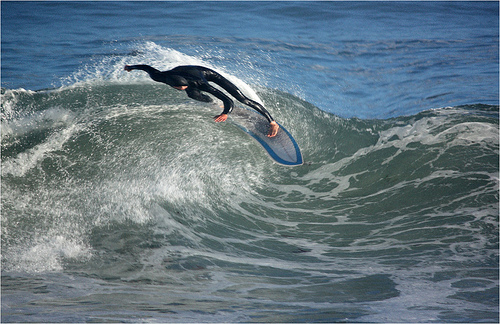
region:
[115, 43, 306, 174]
A person surfing a wave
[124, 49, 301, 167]
surfboarder riding a wave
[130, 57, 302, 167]
man wearing a black wetsuit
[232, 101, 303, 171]
blue and white surfboard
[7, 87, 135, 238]
white spray from the wave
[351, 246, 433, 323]
white foam on the water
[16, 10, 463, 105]
rough blue water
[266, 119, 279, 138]
mans bare foot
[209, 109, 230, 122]
mans bare hand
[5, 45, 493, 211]
small wave on the ocean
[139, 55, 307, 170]
man on a surfboard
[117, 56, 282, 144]
man in wet suit surfing a foamy wave of the ocean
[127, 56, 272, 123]
wet suit the surfer is wearing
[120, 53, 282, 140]
swimmer in a black wet suit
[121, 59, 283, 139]
surfer in a daring pose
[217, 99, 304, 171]
surfers blue and white surf board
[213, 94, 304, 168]
surfers white surf board with blue edge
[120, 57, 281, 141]
bare footed man surfing the waves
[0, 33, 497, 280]
foamy rolling wave the man is riding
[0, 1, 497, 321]
large vast blue ocean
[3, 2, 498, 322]
vast blue ocean the man is surfing in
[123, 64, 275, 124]
a surfers full black wetsuit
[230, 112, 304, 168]
a white and blue surfboard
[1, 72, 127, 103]
the crest of the wave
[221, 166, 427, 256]
the trough of the wave is flat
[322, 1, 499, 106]
blue deep water beyond the waves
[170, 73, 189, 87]
the wetsuit head cover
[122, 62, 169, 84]
the extended arm of the surfer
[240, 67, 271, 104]
the wake from the surfboard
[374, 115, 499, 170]
sea foam formed from the rough water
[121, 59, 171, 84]
the surfers extended arm for balance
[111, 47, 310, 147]
A person in the water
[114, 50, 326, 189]
A person riding a surfboard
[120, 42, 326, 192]
A person riding a surfboard in the water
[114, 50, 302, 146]
Person with a wetsuit on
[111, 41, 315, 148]
Person with a black wetsuit on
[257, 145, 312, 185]
White and blue surfboard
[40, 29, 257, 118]
High waves behind a person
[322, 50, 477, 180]
Waves in the water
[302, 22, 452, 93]
Large body of blue water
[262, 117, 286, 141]
A surfer's bare foot